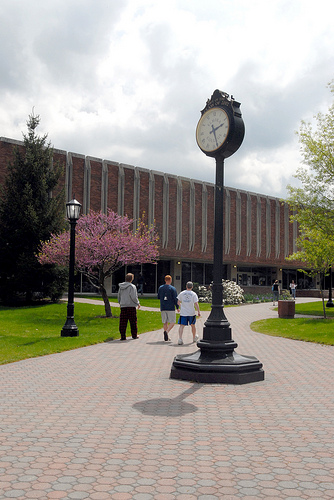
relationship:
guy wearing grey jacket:
[116, 272, 142, 341] [116, 280, 141, 309]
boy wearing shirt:
[176, 280, 202, 348] [174, 289, 198, 319]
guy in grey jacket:
[114, 265, 149, 340] [114, 279, 141, 310]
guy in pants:
[114, 265, 149, 340] [116, 303, 145, 342]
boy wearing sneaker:
[176, 280, 202, 348] [191, 335, 198, 342]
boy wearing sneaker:
[176, 280, 202, 348] [177, 337, 183, 345]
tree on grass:
[0, 103, 69, 310] [2, 296, 178, 358]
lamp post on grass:
[55, 192, 85, 337] [2, 296, 178, 358]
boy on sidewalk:
[176, 280, 202, 348] [93, 330, 171, 402]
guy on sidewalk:
[156, 272, 181, 342] [93, 330, 171, 402]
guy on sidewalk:
[116, 272, 142, 341] [93, 330, 171, 402]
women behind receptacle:
[268, 267, 312, 302] [274, 294, 298, 319]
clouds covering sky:
[0, 3, 332, 198] [1, 2, 325, 207]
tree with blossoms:
[34, 207, 159, 315] [32, 207, 158, 264]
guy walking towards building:
[116, 272, 142, 341] [1, 136, 333, 293]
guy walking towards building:
[156, 273, 180, 337] [1, 136, 333, 293]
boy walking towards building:
[176, 280, 202, 348] [1, 136, 333, 293]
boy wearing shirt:
[172, 276, 206, 349] [176, 289, 199, 316]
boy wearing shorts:
[172, 276, 206, 349] [175, 314, 200, 326]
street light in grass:
[60, 196, 83, 340] [4, 264, 184, 368]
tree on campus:
[0, 103, 69, 307] [1, 295, 333, 499]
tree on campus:
[34, 207, 159, 315] [1, 295, 333, 499]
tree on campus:
[281, 77, 333, 307] [1, 295, 333, 499]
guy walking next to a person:
[116, 272, 142, 341] [158, 273, 175, 340]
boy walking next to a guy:
[176, 280, 202, 348] [156, 272, 181, 342]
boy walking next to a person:
[176, 280, 202, 348] [158, 273, 179, 339]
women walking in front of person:
[270, 278, 281, 306] [286, 276, 301, 307]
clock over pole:
[191, 85, 250, 161] [196, 161, 241, 350]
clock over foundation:
[191, 85, 250, 161] [168, 352, 266, 388]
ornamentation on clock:
[189, 79, 247, 154] [193, 106, 233, 155]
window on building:
[141, 261, 155, 296] [1, 136, 333, 293]